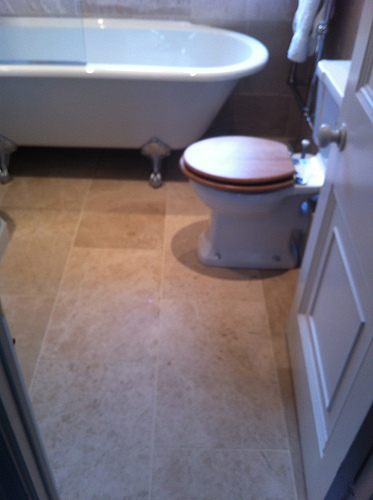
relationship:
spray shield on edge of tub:
[1, 3, 86, 73] [0, 15, 270, 185]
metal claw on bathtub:
[142, 139, 167, 158] [1, 17, 271, 148]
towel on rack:
[286, 0, 335, 62] [284, 1, 338, 126]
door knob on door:
[313, 120, 348, 153] [286, 3, 371, 497]